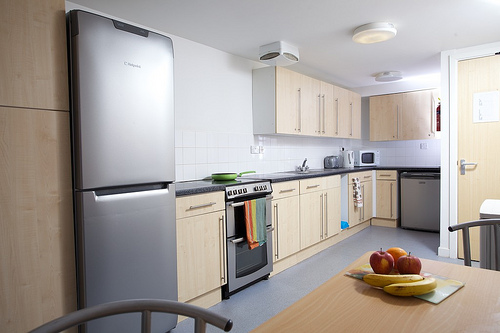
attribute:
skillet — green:
[211, 165, 258, 183]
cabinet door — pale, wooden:
[179, 212, 230, 297]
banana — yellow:
[336, 265, 460, 303]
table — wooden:
[264, 241, 496, 323]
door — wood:
[445, 59, 498, 218]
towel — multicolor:
[244, 199, 266, 249]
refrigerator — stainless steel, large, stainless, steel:
[68, 15, 181, 331]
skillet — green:
[211, 167, 256, 179]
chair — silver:
[1, 266, 236, 331]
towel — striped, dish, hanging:
[237, 200, 277, 249]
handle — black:
[408, 172, 438, 179]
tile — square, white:
[183, 148, 196, 163]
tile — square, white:
[195, 145, 207, 162]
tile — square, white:
[219, 147, 228, 160]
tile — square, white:
[183, 165, 197, 180]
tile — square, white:
[174, 165, 183, 179]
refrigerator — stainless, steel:
[48, 14, 231, 307]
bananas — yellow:
[364, 272, 437, 300]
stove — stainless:
[229, 182, 284, 285]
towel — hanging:
[351, 177, 363, 209]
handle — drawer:
[352, 177, 360, 180]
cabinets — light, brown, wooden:
[246, 61, 441, 146]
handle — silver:
[457, 159, 478, 171]